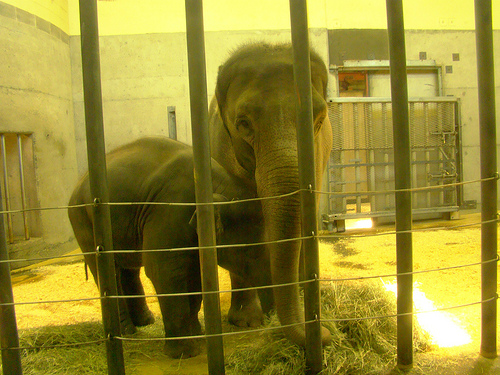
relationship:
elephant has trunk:
[204, 42, 332, 347] [255, 124, 324, 347]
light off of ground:
[368, 285, 478, 356] [352, 236, 484, 351]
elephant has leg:
[65, 133, 293, 358] [119, 269, 151, 326]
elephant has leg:
[65, 133, 293, 358] [81, 259, 137, 334]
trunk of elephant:
[253, 141, 322, 367] [164, 38, 406, 365]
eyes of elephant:
[227, 104, 337, 151] [179, 41, 355, 356]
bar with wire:
[384, 0, 413, 368] [6, 182, 498, 351]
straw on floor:
[27, 242, 434, 372] [8, 225, 494, 372]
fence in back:
[335, 101, 456, 210] [1, 1, 491, 255]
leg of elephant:
[146, 244, 207, 358] [65, 133, 293, 358]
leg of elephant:
[121, 265, 156, 327] [65, 133, 293, 358]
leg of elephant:
[86, 260, 136, 337] [65, 133, 293, 358]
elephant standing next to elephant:
[34, 68, 410, 334] [198, 25, 348, 373]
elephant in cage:
[65, 133, 293, 358] [2, 3, 489, 368]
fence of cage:
[335, 101, 456, 210] [313, 71, 476, 231]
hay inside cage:
[326, 292, 385, 345] [10, 54, 483, 372]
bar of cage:
[387, 2, 412, 369] [2, 3, 489, 368]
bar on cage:
[288, 0, 327, 374] [2, 3, 489, 368]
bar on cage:
[384, 0, 413, 368] [2, 3, 489, 368]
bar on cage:
[473, 0, 498, 360] [2, 3, 489, 368]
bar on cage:
[185, 0, 225, 375] [2, 3, 489, 368]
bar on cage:
[77, 0, 123, 373] [2, 3, 489, 368]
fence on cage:
[337, 85, 472, 194] [2, 3, 489, 368]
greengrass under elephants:
[282, 272, 494, 374] [29, 38, 335, 341]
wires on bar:
[0, 170, 499, 361] [384, 0, 413, 368]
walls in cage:
[97, 32, 192, 152] [2, 3, 489, 368]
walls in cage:
[70, 34, 91, 184] [2, 3, 489, 368]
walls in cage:
[204, 28, 331, 114] [2, 3, 489, 368]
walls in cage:
[402, 28, 482, 214] [2, 3, 489, 368]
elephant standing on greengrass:
[204, 42, 332, 347] [226, 272, 424, 375]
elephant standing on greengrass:
[65, 133, 293, 358] [226, 272, 424, 375]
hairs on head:
[225, 36, 297, 58] [213, 40, 329, 200]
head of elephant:
[213, 40, 329, 200] [204, 42, 332, 347]